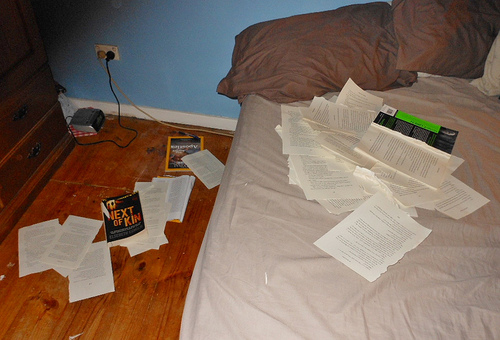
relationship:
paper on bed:
[309, 190, 436, 283] [176, 0, 498, 337]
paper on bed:
[356, 117, 454, 191] [176, 0, 498, 337]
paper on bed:
[286, 150, 367, 202] [176, 0, 498, 337]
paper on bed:
[422, 168, 488, 221] [176, 0, 498, 337]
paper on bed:
[334, 72, 385, 113] [176, 0, 498, 337]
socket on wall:
[88, 44, 126, 66] [36, 0, 231, 123]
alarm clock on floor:
[61, 102, 103, 132] [1, 100, 241, 338]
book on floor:
[102, 190, 145, 247] [131, 277, 146, 308]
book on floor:
[163, 131, 206, 178] [131, 277, 146, 308]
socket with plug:
[91, 41, 121, 62] [105, 52, 117, 61]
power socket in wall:
[87, 40, 128, 73] [33, 0, 391, 131]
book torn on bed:
[276, 79, 484, 285] [176, 0, 498, 337]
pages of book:
[16, 150, 226, 303] [102, 190, 145, 247]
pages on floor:
[16, 150, 226, 303] [1, 100, 241, 338]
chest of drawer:
[0, 2, 76, 245] [27, 79, 66, 111]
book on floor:
[102, 190, 145, 247] [1, 100, 241, 338]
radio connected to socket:
[69, 106, 105, 135] [88, 44, 126, 66]